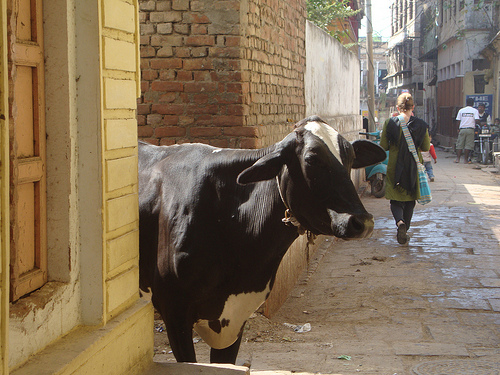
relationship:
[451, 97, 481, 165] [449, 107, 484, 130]
man wearing shirt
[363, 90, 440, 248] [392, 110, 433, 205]
lady carrying bag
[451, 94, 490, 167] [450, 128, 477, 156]
man wearing shorts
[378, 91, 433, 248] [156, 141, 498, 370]
lady walking street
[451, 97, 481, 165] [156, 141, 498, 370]
man standing on street